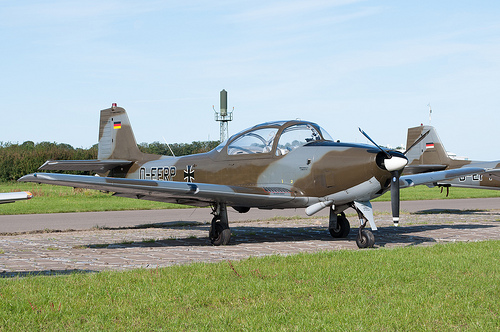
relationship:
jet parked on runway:
[23, 98, 483, 234] [27, 198, 478, 257]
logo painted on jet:
[138, 165, 202, 179] [23, 98, 483, 234]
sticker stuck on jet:
[112, 122, 127, 132] [23, 98, 483, 234]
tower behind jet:
[214, 89, 231, 134] [23, 98, 483, 234]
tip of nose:
[404, 158, 410, 164] [381, 148, 404, 170]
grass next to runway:
[82, 257, 468, 331] [27, 198, 478, 257]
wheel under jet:
[207, 217, 234, 245] [23, 98, 483, 234]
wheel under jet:
[328, 221, 348, 241] [23, 98, 483, 234]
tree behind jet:
[0, 148, 59, 160] [23, 98, 483, 234]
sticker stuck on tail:
[112, 122, 127, 132] [95, 107, 140, 158]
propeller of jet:
[361, 130, 382, 150] [23, 98, 483, 234]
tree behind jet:
[169, 141, 197, 156] [23, 98, 483, 234]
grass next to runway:
[35, 184, 93, 213] [27, 198, 478, 257]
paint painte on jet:
[251, 152, 360, 184] [23, 98, 483, 234]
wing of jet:
[42, 181, 279, 207] [23, 98, 483, 234]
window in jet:
[235, 133, 269, 153] [23, 98, 483, 234]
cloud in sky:
[386, 38, 488, 67] [10, 6, 489, 77]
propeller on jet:
[411, 131, 433, 146] [23, 98, 483, 234]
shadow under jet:
[234, 222, 324, 242] [23, 98, 483, 234]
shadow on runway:
[419, 208, 477, 216] [27, 198, 478, 257]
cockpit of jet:
[229, 118, 326, 149] [23, 98, 483, 234]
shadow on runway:
[234, 222, 324, 242] [27, 198, 478, 257]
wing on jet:
[42, 181, 279, 207] [23, 98, 483, 234]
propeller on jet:
[388, 176, 403, 228] [23, 98, 483, 234]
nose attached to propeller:
[381, 148, 404, 170] [388, 176, 403, 228]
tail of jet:
[95, 107, 140, 158] [23, 98, 483, 234]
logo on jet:
[138, 165, 202, 179] [23, 98, 483, 234]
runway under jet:
[27, 198, 478, 257] [23, 98, 483, 234]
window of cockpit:
[235, 133, 269, 153] [229, 118, 326, 149]